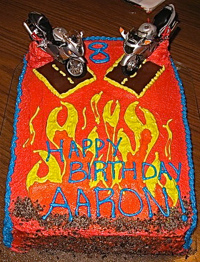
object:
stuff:
[12, 203, 190, 256]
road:
[102, 48, 166, 99]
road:
[32, 50, 97, 99]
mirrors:
[142, 38, 154, 46]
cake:
[3, 35, 197, 254]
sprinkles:
[55, 218, 146, 230]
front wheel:
[65, 58, 87, 79]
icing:
[179, 83, 196, 183]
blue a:
[75, 188, 91, 218]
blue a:
[42, 186, 72, 221]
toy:
[23, 9, 87, 79]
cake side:
[6, 220, 195, 260]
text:
[43, 135, 189, 223]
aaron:
[43, 186, 171, 221]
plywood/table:
[57, 1, 126, 22]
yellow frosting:
[22, 91, 179, 210]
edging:
[188, 180, 197, 227]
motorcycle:
[120, 3, 179, 77]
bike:
[22, 10, 87, 80]